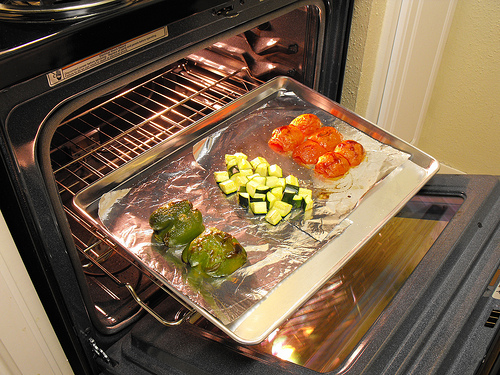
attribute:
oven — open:
[44, 79, 499, 374]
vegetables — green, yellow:
[216, 150, 314, 225]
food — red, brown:
[268, 114, 389, 182]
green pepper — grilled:
[180, 228, 247, 278]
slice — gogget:
[249, 199, 268, 217]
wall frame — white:
[366, 5, 453, 145]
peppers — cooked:
[146, 197, 206, 249]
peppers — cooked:
[180, 227, 249, 279]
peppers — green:
[110, 180, 260, 282]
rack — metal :
[40, 104, 152, 201]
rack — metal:
[120, 98, 155, 121]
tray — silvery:
[150, 133, 346, 286]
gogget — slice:
[264, 207, 282, 224]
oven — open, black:
[1, 1, 497, 373]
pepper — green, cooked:
[162, 214, 270, 298]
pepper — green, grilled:
[151, 198, 203, 249]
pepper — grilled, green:
[183, 226, 254, 283]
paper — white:
[100, 87, 415, 334]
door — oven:
[396, 233, 466, 272]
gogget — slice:
[223, 148, 245, 160]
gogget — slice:
[234, 157, 249, 169]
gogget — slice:
[211, 168, 233, 182]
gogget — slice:
[217, 179, 237, 196]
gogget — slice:
[245, 181, 262, 193]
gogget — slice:
[252, 161, 268, 176]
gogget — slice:
[264, 160, 283, 178]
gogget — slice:
[265, 175, 281, 189]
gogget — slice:
[272, 199, 297, 219]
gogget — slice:
[298, 195, 313, 210]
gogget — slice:
[279, 190, 298, 202]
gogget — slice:
[283, 172, 300, 187]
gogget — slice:
[267, 184, 284, 195]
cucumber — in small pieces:
[212, 147, 315, 226]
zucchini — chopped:
[218, 150, 318, 227]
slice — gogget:
[275, 201, 296, 216]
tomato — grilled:
[272, 111, 369, 183]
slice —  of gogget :
[214, 169, 228, 184]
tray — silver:
[71, 74, 440, 346]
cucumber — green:
[217, 157, 314, 226]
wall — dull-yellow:
[452, 32, 495, 167]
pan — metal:
[69, 71, 443, 346]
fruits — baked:
[149, 200, 247, 277]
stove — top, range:
[0, 0, 498, 373]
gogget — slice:
[263, 175, 313, 205]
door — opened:
[112, 89, 497, 360]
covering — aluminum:
[116, 106, 392, 278]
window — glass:
[0, 0, 498, 370]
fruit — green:
[179, 228, 248, 279]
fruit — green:
[150, 196, 208, 246]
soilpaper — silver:
[85, 90, 414, 326]